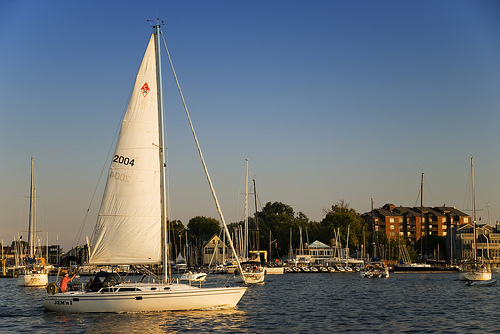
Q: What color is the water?
A: Blue.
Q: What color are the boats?
A: White.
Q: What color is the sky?
A: Blue and orange.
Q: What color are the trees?
A: Green.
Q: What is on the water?
A: Boats.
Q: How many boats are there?
A: Six.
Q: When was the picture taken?
A: Daytime.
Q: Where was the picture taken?
A: At a marina.